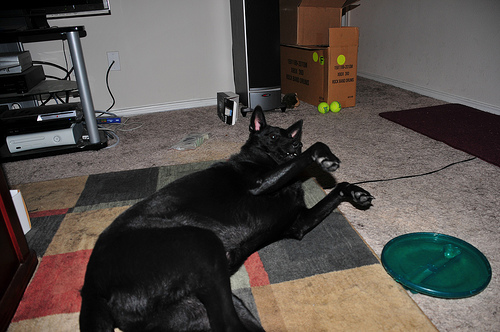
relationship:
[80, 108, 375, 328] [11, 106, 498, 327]
dog lying on floor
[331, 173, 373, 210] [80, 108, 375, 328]
paw of a dog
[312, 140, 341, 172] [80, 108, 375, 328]
paw of a dog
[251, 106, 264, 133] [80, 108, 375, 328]
ear of a dog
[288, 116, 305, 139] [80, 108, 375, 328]
ear of a dog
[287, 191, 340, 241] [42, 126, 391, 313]
leg of a dog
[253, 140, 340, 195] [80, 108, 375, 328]
leg of dog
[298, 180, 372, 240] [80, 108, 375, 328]
leg of dog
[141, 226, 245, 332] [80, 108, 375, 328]
back leg of dog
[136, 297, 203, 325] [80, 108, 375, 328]
leg of dog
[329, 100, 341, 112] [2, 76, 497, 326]
ball on a floor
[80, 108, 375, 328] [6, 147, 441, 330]
dog lying on mat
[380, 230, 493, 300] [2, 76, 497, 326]
plate on floor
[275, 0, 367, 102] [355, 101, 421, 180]
boxes standing on floor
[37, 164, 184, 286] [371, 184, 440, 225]
rug on floor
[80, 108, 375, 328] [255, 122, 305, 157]
dog has face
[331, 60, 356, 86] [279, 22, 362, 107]
text printed on box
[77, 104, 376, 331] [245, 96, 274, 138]
dog has ear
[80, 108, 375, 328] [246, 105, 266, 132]
dog has ear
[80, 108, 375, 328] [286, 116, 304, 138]
dog has ear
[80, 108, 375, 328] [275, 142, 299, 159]
dog has nose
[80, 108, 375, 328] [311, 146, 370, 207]
dog has paws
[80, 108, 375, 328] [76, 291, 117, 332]
dog has dog's tail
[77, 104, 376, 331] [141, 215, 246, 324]
dog has back leg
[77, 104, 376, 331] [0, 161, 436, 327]
dog has rug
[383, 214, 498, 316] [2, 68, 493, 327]
frisbee on ground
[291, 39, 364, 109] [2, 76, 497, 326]
cardboard on floor